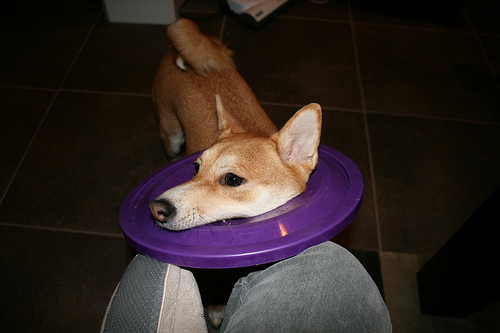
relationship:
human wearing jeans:
[220, 238, 395, 331] [211, 237, 392, 328]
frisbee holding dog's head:
[116, 139, 363, 269] [150, 91, 324, 228]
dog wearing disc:
[146, 14, 326, 260] [114, 132, 367, 270]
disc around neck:
[114, 132, 367, 270] [239, 201, 335, 229]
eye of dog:
[219, 172, 247, 187] [146, 26, 351, 237]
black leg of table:
[419, 208, 485, 307] [411, 229, 466, 284]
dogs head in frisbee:
[144, 94, 324, 234] [116, 139, 363, 269]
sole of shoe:
[90, 241, 167, 331] [98, 249, 210, 331]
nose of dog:
[147, 197, 178, 222] [149, 17, 321, 242]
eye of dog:
[219, 171, 248, 186] [148, 92, 323, 231]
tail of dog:
[162, 13, 245, 80] [146, 14, 326, 260]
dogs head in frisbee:
[112, 94, 324, 229] [94, 145, 384, 263]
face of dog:
[123, 85, 445, 254] [84, 91, 374, 239]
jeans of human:
[251, 234, 397, 331] [220, 241, 394, 331]